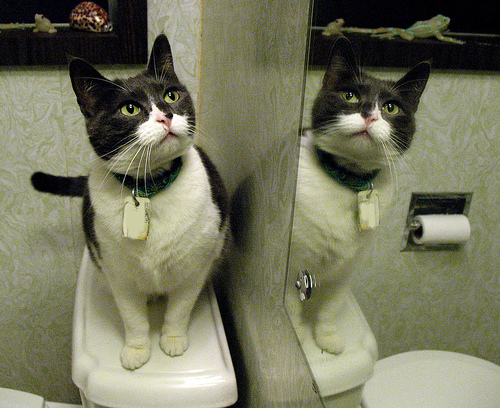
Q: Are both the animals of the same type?
A: No, they are frogs and cats.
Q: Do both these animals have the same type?
A: No, they are frogs and cats.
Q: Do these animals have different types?
A: Yes, they are frogs and cats.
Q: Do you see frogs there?
A: Yes, there is a frog.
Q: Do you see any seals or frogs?
A: Yes, there is a frog.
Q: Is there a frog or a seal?
A: Yes, there is a frog.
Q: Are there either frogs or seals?
A: Yes, there is a frog.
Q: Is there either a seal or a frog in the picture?
A: Yes, there is a frog.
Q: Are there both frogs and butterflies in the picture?
A: No, there is a frog but no butterflies.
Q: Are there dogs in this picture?
A: No, there are no dogs.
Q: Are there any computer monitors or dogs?
A: No, there are no dogs or computer monitors.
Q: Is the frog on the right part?
A: Yes, the frog is on the right of the image.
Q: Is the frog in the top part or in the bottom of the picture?
A: The frog is in the top of the image.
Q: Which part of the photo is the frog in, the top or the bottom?
A: The frog is in the top of the image.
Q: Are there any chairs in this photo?
A: No, there are no chairs.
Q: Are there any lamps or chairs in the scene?
A: No, there are no chairs or lamps.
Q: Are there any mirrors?
A: Yes, there is a mirror.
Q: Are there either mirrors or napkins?
A: Yes, there is a mirror.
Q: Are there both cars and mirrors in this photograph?
A: No, there is a mirror but no cars.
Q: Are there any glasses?
A: No, there are no glasses.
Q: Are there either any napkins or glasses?
A: No, there are no glasses or napkins.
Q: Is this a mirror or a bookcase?
A: This is a mirror.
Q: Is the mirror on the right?
A: Yes, the mirror is on the right of the image.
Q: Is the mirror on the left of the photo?
A: No, the mirror is on the right of the image.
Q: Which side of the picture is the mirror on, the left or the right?
A: The mirror is on the right of the image.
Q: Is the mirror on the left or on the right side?
A: The mirror is on the right of the image.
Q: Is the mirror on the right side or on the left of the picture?
A: The mirror is on the right of the image.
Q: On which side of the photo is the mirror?
A: The mirror is on the right of the image.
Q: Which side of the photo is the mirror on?
A: The mirror is on the right of the image.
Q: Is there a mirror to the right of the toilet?
A: Yes, there is a mirror to the right of the toilet.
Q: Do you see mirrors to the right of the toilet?
A: Yes, there is a mirror to the right of the toilet.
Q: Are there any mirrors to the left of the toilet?
A: No, the mirror is to the right of the toilet.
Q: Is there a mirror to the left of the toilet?
A: No, the mirror is to the right of the toilet.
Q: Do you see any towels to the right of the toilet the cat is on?
A: No, there is a mirror to the right of the toilet.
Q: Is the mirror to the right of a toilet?
A: Yes, the mirror is to the right of a toilet.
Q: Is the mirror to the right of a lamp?
A: No, the mirror is to the right of a toilet.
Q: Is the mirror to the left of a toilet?
A: No, the mirror is to the right of a toilet.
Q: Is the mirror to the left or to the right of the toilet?
A: The mirror is to the right of the toilet.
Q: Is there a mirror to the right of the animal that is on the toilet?
A: Yes, there is a mirror to the right of the cat.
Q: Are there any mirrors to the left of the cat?
A: No, the mirror is to the right of the cat.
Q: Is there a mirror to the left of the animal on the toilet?
A: No, the mirror is to the right of the cat.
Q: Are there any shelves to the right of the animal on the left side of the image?
A: No, there is a mirror to the right of the cat.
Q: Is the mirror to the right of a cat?
A: Yes, the mirror is to the right of a cat.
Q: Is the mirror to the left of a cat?
A: No, the mirror is to the right of a cat.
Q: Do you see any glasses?
A: No, there are no glasses.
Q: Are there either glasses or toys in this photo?
A: No, there are no glasses or toys.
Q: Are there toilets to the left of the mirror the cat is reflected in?
A: Yes, there is a toilet to the left of the mirror.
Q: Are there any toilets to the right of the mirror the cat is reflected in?
A: No, the toilet is to the left of the mirror.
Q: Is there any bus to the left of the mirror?
A: No, there is a toilet to the left of the mirror.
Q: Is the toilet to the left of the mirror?
A: Yes, the toilet is to the left of the mirror.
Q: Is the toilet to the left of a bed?
A: No, the toilet is to the left of the mirror.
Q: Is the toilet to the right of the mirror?
A: No, the toilet is to the left of the mirror.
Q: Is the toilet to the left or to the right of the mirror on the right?
A: The toilet is to the left of the mirror.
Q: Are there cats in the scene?
A: Yes, there is a cat.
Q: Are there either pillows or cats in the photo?
A: Yes, there is a cat.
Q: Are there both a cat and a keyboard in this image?
A: No, there is a cat but no keyboards.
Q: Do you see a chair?
A: No, there are no chairs.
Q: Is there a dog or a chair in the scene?
A: No, there are no chairs or dogs.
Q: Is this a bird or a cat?
A: This is a cat.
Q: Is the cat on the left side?
A: Yes, the cat is on the left of the image.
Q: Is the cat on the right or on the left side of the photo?
A: The cat is on the left of the image.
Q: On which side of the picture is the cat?
A: The cat is on the left of the image.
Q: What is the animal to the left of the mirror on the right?
A: The animal is a cat.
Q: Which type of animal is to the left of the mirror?
A: The animal is a cat.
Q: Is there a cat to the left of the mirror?
A: Yes, there is a cat to the left of the mirror.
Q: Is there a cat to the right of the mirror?
A: No, the cat is to the left of the mirror.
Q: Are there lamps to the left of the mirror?
A: No, there is a cat to the left of the mirror.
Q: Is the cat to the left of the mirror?
A: Yes, the cat is to the left of the mirror.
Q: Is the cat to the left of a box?
A: No, the cat is to the left of the mirror.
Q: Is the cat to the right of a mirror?
A: No, the cat is to the left of a mirror.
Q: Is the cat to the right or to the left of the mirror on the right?
A: The cat is to the left of the mirror.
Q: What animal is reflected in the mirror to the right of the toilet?
A: The cat is reflected in the mirror.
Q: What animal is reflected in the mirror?
A: The cat is reflected in the mirror.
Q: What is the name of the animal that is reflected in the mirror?
A: The animal is a cat.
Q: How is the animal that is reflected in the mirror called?
A: The animal is a cat.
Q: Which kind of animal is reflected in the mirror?
A: The animal is a cat.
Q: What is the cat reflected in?
A: The cat is reflected in the mirror.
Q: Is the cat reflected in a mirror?
A: Yes, the cat is reflected in a mirror.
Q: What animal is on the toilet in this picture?
A: The cat is on the toilet.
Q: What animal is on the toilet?
A: The cat is on the toilet.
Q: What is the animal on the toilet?
A: The animal is a cat.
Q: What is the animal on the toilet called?
A: The animal is a cat.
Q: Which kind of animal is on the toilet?
A: The animal is a cat.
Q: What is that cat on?
A: The cat is on the toilet.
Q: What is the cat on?
A: The cat is on the toilet.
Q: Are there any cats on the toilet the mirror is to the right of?
A: Yes, there is a cat on the toilet.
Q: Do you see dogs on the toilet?
A: No, there is a cat on the toilet.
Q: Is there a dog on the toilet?
A: No, there is a cat on the toilet.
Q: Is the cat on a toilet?
A: Yes, the cat is on a toilet.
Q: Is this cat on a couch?
A: No, the cat is on a toilet.